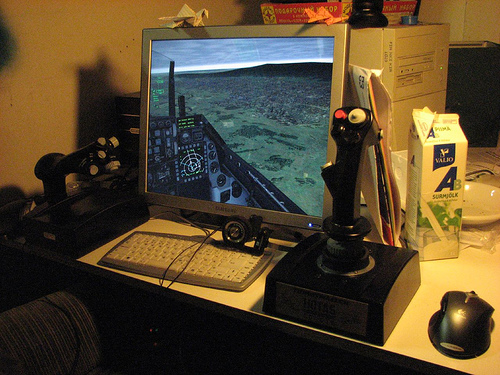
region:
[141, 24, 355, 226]
Computer monitor on top of a table.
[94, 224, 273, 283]
Computer keyboard seated on a table.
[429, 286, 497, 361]
Black colored mouse on table.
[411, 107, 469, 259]
Milk in a packet on table.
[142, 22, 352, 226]
Computer monitor with screen on.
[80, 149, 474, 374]
A white table top with items on it.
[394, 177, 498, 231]
A white ceramic plate behind milk packet.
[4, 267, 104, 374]
Part of a chair next to the table.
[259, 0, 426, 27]
Small cartoons behind the monitor.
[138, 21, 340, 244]
a computer monitor on desk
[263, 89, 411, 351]
a joystick controller for games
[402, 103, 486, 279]
a container of milk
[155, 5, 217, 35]
an origami swan on top of monitor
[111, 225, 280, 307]
a keyboard for the computer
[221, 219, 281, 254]
a black webcam for computer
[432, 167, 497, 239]
a white bowl behind the milk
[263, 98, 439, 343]
a black joystick controller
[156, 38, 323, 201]
a game on the monitor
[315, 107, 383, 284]
Handle of game controller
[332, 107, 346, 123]
Red button on game controller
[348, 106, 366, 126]
White button on controller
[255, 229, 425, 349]
Base of the controller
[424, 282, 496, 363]
Black mouse on desk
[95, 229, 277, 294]
Gray and white keyboard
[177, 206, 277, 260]
Black headphones on desk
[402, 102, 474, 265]
White carton on desk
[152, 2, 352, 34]
Oragami designs on monitor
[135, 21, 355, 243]
Silver computer screen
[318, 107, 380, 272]
black joystick for gaming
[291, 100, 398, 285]
a controller for gaming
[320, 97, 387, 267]
a joystick for gaming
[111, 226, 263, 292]
a wired computer keyboard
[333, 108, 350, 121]
red button on joystick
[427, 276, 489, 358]
a black computer mouse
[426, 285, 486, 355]
a Logitech computer mouse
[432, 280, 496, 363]
a wireless computer mouse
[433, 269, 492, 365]
black Logitech computer mouse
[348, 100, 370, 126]
white button on joystick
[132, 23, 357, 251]
the computer is on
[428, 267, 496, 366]
the mouse is black in colour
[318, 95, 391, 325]
the joystick ids black in clour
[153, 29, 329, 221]
a computer game is on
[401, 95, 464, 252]
the pack is white in colour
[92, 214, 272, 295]
the keyboard is white in colour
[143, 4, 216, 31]
a paper is folded on top of the monitor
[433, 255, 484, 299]
the table is white in colour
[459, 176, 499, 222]
the plate is white and circular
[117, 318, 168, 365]
the ligts are on